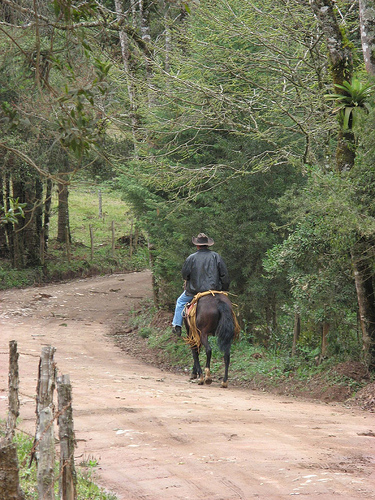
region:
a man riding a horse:
[170, 229, 243, 387]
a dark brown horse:
[181, 285, 237, 386]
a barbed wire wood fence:
[0, 337, 83, 493]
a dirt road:
[1, 252, 371, 495]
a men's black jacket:
[181, 246, 226, 292]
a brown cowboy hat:
[189, 232, 213, 246]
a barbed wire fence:
[10, 219, 147, 259]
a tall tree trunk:
[316, 3, 372, 365]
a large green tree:
[114, 25, 313, 329]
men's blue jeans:
[170, 287, 193, 327]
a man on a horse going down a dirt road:
[165, 232, 235, 386]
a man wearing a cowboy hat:
[192, 230, 218, 254]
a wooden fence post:
[56, 375, 71, 499]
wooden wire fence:
[0, 345, 88, 497]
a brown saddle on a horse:
[183, 284, 243, 341]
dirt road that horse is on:
[1, 275, 273, 490]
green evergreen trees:
[296, 135, 374, 361]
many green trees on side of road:
[0, 1, 374, 404]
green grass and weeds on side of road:
[136, 300, 341, 394]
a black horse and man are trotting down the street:
[167, 226, 248, 385]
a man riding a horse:
[159, 227, 256, 408]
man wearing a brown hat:
[172, 221, 234, 277]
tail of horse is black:
[207, 295, 243, 355]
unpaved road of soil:
[2, 258, 366, 494]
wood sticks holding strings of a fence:
[1, 333, 85, 498]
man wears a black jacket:
[166, 227, 238, 303]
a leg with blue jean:
[165, 285, 192, 345]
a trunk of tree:
[312, 10, 373, 388]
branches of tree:
[110, 19, 339, 180]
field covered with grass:
[65, 192, 136, 263]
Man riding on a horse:
[153, 214, 251, 391]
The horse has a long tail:
[214, 302, 242, 354]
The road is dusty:
[90, 360, 226, 486]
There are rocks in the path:
[20, 277, 107, 319]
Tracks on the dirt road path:
[113, 395, 221, 495]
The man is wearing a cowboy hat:
[181, 232, 237, 295]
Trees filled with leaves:
[171, 79, 338, 227]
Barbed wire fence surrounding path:
[11, 344, 114, 498]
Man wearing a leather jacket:
[172, 249, 232, 289]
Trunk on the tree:
[339, 245, 374, 369]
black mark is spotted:
[161, 483, 175, 491]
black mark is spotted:
[166, 482, 183, 488]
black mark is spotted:
[166, 475, 183, 494]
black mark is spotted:
[159, 484, 176, 496]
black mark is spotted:
[168, 482, 174, 494]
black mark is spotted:
[162, 481, 180, 498]